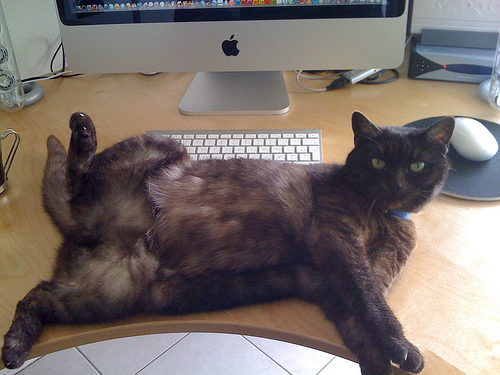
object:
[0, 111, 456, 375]
cat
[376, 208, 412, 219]
collar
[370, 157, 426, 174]
eyes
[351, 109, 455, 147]
ears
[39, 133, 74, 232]
tail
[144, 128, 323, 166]
keybaord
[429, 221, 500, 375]
desk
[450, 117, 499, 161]
mouse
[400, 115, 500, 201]
pad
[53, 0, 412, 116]
computer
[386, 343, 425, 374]
paw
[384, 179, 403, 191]
nose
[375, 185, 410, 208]
mouth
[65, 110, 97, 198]
foot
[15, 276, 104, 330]
leg